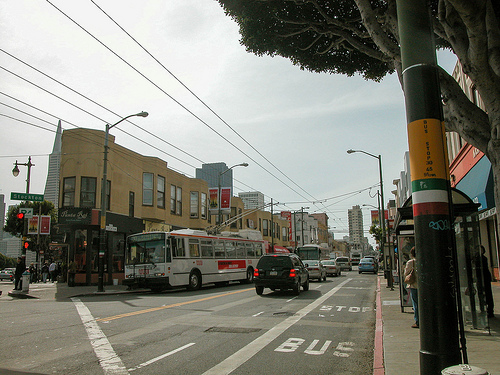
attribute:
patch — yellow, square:
[396, 124, 498, 209]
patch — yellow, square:
[408, 115, 451, 180]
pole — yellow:
[394, 0, 464, 372]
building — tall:
[346, 203, 365, 259]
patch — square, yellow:
[403, 115, 449, 185]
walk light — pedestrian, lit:
[18, 238, 32, 263]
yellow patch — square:
[98, 215, 107, 230]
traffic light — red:
[13, 212, 32, 241]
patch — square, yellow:
[219, 187, 233, 218]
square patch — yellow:
[405, 122, 445, 183]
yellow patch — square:
[405, 118, 447, 178]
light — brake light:
[250, 267, 260, 274]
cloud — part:
[159, 2, 214, 57]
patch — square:
[401, 115, 454, 185]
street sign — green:
[7, 186, 47, 206]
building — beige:
[53, 139, 263, 240]